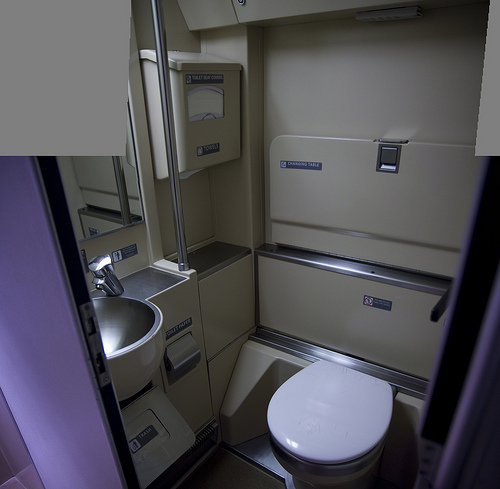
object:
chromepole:
[147, 1, 192, 275]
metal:
[258, 256, 445, 295]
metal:
[100, 296, 137, 348]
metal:
[292, 344, 397, 379]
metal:
[245, 436, 278, 471]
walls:
[388, 157, 498, 487]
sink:
[90, 295, 167, 402]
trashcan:
[171, 240, 251, 275]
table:
[251, 135, 485, 381]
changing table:
[270, 134, 489, 276]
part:
[195, 241, 264, 268]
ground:
[418, 149, 445, 179]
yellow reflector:
[198, 254, 256, 362]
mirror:
[38, 82, 151, 240]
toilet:
[262, 360, 392, 489]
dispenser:
[164, 332, 201, 380]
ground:
[283, 53, 318, 90]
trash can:
[172, 235, 255, 360]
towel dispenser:
[139, 48, 241, 180]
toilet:
[266, 361, 393, 464]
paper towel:
[187, 84, 224, 122]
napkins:
[170, 165, 213, 185]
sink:
[88, 295, 164, 360]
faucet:
[87, 253, 124, 297]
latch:
[376, 138, 409, 174]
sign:
[128, 424, 158, 454]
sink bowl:
[87, 290, 163, 402]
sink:
[90, 250, 193, 388]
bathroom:
[6, 9, 483, 478]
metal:
[90, 260, 130, 302]